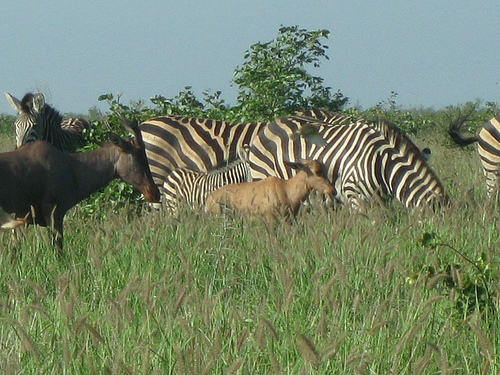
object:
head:
[103, 118, 164, 204]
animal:
[442, 100, 499, 206]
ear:
[3, 91, 31, 114]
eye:
[135, 159, 145, 167]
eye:
[30, 123, 39, 131]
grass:
[0, 99, 500, 375]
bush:
[67, 22, 350, 226]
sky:
[0, 0, 500, 116]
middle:
[127, 0, 361, 375]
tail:
[444, 106, 480, 148]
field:
[0, 111, 500, 375]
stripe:
[138, 123, 200, 173]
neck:
[382, 140, 447, 205]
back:
[475, 111, 500, 209]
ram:
[200, 158, 338, 228]